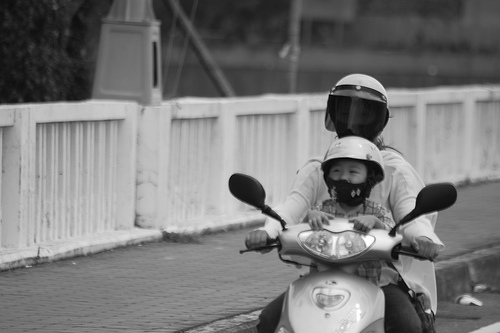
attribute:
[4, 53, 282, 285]
fence — white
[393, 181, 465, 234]
rearview mirror — black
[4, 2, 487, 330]
photo — black and white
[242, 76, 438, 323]
woman — wearing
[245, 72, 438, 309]
mother — wearing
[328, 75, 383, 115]
person's helmet — white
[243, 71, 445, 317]
person — wearing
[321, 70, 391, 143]
helmet — full face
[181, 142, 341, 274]
mirror — back, rear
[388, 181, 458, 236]
mirror — rear, view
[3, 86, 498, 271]
railing — white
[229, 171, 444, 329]
scooter — headlight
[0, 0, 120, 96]
image — blurry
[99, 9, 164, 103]
pole — metal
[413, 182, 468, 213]
mirror — side 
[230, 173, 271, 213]
mirror — side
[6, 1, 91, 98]
tree — blurry